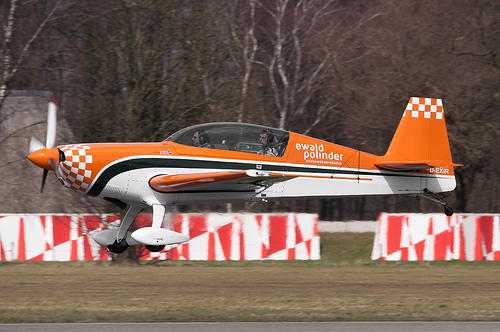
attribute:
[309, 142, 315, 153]
letter — white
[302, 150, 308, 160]
letter — white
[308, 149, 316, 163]
letter — white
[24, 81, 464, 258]
plane — orange, white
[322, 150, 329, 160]
letter — white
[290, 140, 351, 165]
letters — white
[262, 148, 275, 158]
shirt — striped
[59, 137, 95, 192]
pattern — plaid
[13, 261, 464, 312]
grass — dry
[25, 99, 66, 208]
propeller — moving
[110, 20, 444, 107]
trees — bare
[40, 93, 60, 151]
blade — grey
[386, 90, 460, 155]
stabilizer — vertical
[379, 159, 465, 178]
stabilizer — horizontal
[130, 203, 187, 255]
structure — white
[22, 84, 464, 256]
aircraft — white, orange, small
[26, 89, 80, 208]
propeller — large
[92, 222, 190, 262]
landing gear — planes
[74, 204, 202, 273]
gear — rear planes landing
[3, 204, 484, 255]
banner — white checkered, red 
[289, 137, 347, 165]
name — imprinted  bare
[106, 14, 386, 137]
trees — large brown bare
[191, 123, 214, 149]
man — 2 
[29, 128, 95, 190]
nose — Orange 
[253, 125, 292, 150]
seat — back 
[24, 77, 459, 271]
airplane . — Orange  , written on side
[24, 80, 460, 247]
airplane — orange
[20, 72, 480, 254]
airplane — orange , white 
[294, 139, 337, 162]
letters — white 